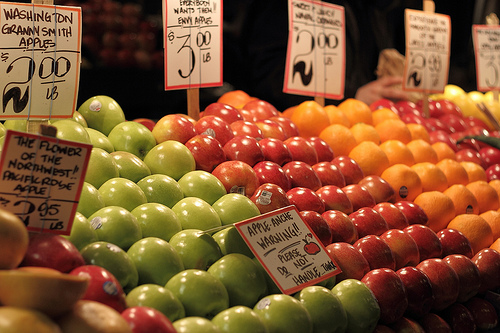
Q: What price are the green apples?
A: $2.00 LB.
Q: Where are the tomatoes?
A: Beside the oranges.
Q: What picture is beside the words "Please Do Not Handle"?
A: Apple.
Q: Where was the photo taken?
A: At a fruit stand.